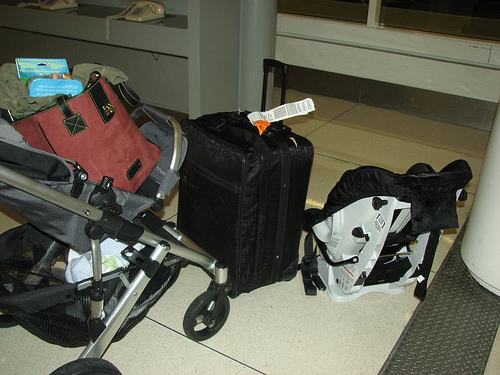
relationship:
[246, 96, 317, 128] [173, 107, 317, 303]
luggage sticker on suitcase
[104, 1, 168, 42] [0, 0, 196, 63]
corded telephone on shelf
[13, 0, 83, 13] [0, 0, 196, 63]
corded telephone on shelf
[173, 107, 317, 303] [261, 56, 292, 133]
suitcase has handle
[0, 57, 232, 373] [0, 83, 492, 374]
baby stroller on floor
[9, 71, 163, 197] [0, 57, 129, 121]
bag has goods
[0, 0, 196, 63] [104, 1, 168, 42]
shelf has corded telephone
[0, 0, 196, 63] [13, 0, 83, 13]
shelf has corded telephone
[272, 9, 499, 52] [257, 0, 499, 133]
window seal in background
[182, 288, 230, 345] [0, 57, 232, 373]
wheel on baby stroller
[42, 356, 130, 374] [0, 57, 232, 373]
wheel on baby stroller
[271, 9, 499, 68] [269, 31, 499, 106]
windowsill has base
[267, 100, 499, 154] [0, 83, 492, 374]
seam in floor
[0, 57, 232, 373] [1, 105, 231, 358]
baby stroller has aluminum frame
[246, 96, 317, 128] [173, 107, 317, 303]
luggage sticker on luggage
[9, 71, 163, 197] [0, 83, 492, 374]
bag on floor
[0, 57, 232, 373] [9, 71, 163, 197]
baby stroller has luggage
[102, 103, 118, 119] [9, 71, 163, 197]
latch on bag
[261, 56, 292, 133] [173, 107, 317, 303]
handle on luggage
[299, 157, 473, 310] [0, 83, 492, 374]
car seat on floor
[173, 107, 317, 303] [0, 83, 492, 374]
luggage on floor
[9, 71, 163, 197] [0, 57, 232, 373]
bag on baby stroller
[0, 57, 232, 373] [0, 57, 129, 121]
baby stroller has items